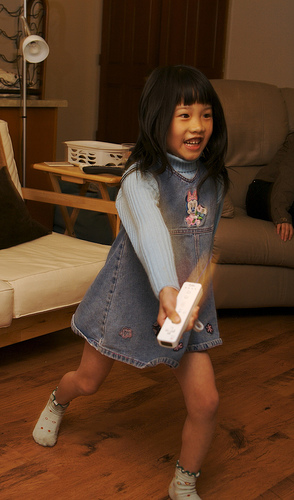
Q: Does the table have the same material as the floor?
A: Yes, both the table and the floor are made of wood.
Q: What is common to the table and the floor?
A: The material, both the table and the floor are wooden.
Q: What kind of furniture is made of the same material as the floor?
A: The table is made of the same material as the floor.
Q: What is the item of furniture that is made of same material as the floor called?
A: The piece of furniture is a table.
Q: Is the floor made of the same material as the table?
A: Yes, both the floor and the table are made of wood.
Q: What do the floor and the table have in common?
A: The material, both the floor and the table are wooden.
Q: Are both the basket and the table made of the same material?
A: No, the basket is made of plastic and the table is made of wood.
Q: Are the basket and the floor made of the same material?
A: No, the basket is made of plastic and the floor is made of wood.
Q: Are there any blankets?
A: Yes, there is a blanket.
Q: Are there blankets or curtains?
A: Yes, there is a blanket.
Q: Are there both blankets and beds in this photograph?
A: No, there is a blanket but no beds.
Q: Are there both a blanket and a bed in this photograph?
A: No, there is a blanket but no beds.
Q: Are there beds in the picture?
A: No, there are no beds.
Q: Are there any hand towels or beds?
A: No, there are no beds or hand towels.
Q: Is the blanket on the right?
A: Yes, the blanket is on the right of the image.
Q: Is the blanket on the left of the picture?
A: No, the blanket is on the right of the image.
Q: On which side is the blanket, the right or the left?
A: The blanket is on the right of the image.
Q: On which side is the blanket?
A: The blanket is on the right of the image.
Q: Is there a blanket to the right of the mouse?
A: Yes, there is a blanket to the right of the mouse.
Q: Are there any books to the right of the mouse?
A: No, there is a blanket to the right of the mouse.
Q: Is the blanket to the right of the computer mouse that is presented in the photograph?
A: Yes, the blanket is to the right of the computer mouse.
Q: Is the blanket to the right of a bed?
A: No, the blanket is to the right of the computer mouse.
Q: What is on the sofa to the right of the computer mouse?
A: The blanket is on the sofa.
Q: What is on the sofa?
A: The blanket is on the sofa.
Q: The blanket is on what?
A: The blanket is on the sofa.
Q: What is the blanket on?
A: The blanket is on the sofa.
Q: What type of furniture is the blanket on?
A: The blanket is on the sofa.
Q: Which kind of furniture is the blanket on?
A: The blanket is on the sofa.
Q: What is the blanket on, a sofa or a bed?
A: The blanket is on a sofa.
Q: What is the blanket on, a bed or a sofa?
A: The blanket is on a sofa.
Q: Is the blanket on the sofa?
A: Yes, the blanket is on the sofa.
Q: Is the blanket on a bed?
A: No, the blanket is on the sofa.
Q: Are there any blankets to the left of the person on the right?
A: Yes, there is a blanket to the left of the person.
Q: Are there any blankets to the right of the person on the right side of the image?
A: No, the blanket is to the left of the person.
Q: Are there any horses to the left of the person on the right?
A: No, there is a blanket to the left of the person.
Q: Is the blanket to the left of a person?
A: Yes, the blanket is to the left of a person.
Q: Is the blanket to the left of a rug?
A: No, the blanket is to the left of a person.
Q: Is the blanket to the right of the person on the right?
A: No, the blanket is to the left of the person.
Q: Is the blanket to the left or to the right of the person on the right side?
A: The blanket is to the left of the person.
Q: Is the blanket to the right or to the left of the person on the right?
A: The blanket is to the left of the person.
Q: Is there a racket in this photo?
A: No, there are no rackets.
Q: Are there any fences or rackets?
A: No, there are no rackets or fences.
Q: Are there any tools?
A: No, there are no tools.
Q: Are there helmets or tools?
A: No, there are no tools or helmets.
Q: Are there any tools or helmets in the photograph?
A: No, there are no tools or helmets.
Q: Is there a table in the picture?
A: Yes, there is a table.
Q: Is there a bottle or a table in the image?
A: Yes, there is a table.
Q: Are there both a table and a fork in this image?
A: No, there is a table but no forks.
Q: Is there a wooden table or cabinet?
A: Yes, there is a wood table.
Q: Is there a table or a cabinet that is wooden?
A: Yes, the table is wooden.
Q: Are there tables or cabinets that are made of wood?
A: Yes, the table is made of wood.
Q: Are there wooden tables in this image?
A: Yes, there is a wood table.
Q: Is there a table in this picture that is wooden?
A: Yes, there is a table that is wooden.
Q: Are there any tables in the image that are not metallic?
A: Yes, there is a wooden table.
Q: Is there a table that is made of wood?
A: Yes, there is a table that is made of wood.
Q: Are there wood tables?
A: Yes, there is a table that is made of wood.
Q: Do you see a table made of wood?
A: Yes, there is a table that is made of wood.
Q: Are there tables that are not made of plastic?
A: Yes, there is a table that is made of wood.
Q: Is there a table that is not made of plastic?
A: Yes, there is a table that is made of wood.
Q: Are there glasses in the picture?
A: No, there are no glasses.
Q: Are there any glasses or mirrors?
A: No, there are no glasses or mirrors.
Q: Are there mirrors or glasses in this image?
A: No, there are no glasses or mirrors.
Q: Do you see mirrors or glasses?
A: No, there are no glasses or mirrors.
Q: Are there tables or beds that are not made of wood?
A: No, there is a table but it is made of wood.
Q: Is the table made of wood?
A: Yes, the table is made of wood.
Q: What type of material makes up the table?
A: The table is made of wood.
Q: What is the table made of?
A: The table is made of wood.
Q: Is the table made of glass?
A: No, the table is made of wood.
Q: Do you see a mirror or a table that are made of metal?
A: No, there is a table but it is made of wood.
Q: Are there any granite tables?
A: No, there is a table but it is made of wood.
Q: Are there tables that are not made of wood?
A: No, there is a table but it is made of wood.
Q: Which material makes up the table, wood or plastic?
A: The table is made of wood.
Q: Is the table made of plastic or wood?
A: The table is made of wood.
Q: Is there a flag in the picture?
A: No, there are no flags.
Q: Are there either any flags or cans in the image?
A: No, there are no flags or cans.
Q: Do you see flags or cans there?
A: No, there are no flags or cans.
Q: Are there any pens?
A: No, there are no pens.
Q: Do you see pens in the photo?
A: No, there are no pens.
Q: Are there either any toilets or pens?
A: No, there are no pens or toilets.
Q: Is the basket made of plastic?
A: Yes, the basket is made of plastic.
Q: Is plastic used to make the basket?
A: Yes, the basket is made of plastic.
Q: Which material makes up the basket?
A: The basket is made of plastic.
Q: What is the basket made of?
A: The basket is made of plastic.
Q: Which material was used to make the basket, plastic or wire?
A: The basket is made of plastic.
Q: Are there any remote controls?
A: Yes, there is a remote control.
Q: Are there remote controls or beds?
A: Yes, there is a remote control.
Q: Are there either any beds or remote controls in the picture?
A: Yes, there is a remote control.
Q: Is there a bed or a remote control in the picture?
A: Yes, there is a remote control.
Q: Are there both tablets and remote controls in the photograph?
A: No, there is a remote control but no tablets.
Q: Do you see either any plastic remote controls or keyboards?
A: Yes, there is a plastic remote control.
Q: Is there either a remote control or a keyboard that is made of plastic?
A: Yes, the remote control is made of plastic.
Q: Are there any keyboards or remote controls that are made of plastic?
A: Yes, the remote control is made of plastic.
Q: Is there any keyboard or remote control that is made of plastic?
A: Yes, the remote control is made of plastic.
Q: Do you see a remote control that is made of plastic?
A: Yes, there is a remote control that is made of plastic.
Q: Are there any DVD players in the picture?
A: No, there are no DVD players.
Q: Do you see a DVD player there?
A: No, there are no DVD players.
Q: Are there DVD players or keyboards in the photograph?
A: No, there are no DVD players or keyboards.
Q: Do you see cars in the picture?
A: No, there are no cars.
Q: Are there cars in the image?
A: No, there are no cars.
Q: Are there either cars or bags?
A: No, there are no cars or bags.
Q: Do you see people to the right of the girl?
A: Yes, there is a person to the right of the girl.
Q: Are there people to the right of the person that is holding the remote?
A: Yes, there is a person to the right of the girl.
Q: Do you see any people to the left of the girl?
A: No, the person is to the right of the girl.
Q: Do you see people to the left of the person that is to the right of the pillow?
A: No, the person is to the right of the girl.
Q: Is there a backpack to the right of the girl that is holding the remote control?
A: No, there is a person to the right of the girl.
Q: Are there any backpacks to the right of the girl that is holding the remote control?
A: No, there is a person to the right of the girl.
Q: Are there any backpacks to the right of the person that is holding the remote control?
A: No, there is a person to the right of the girl.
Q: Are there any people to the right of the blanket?
A: Yes, there is a person to the right of the blanket.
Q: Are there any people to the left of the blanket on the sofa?
A: No, the person is to the right of the blanket.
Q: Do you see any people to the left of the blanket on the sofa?
A: No, the person is to the right of the blanket.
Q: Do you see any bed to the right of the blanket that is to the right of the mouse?
A: No, there is a person to the right of the blanket.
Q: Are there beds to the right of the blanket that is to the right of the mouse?
A: No, there is a person to the right of the blanket.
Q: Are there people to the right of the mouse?
A: Yes, there is a person to the right of the mouse.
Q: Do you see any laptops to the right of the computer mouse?
A: No, there is a person to the right of the computer mouse.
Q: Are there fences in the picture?
A: No, there are no fences.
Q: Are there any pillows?
A: Yes, there is a pillow.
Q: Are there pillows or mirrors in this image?
A: Yes, there is a pillow.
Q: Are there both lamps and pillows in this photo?
A: Yes, there are both a pillow and a lamp.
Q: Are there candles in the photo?
A: No, there are no candles.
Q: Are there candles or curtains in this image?
A: No, there are no candles or curtains.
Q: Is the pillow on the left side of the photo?
A: Yes, the pillow is on the left of the image.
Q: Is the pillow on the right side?
A: No, the pillow is on the left of the image.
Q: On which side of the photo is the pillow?
A: The pillow is on the left of the image.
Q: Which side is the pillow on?
A: The pillow is on the left of the image.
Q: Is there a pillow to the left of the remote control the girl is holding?
A: Yes, there is a pillow to the left of the remote control.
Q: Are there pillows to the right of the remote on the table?
A: No, the pillow is to the left of the remote control.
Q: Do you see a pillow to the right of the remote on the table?
A: No, the pillow is to the left of the remote control.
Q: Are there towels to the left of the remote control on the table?
A: No, there is a pillow to the left of the remote.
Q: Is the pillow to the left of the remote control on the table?
A: Yes, the pillow is to the left of the remote.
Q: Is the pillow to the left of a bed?
A: No, the pillow is to the left of the remote.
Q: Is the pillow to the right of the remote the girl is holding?
A: No, the pillow is to the left of the remote control.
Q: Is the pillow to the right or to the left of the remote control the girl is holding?
A: The pillow is to the left of the remote.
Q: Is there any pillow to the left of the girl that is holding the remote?
A: Yes, there is a pillow to the left of the girl.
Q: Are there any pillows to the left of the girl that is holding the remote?
A: Yes, there is a pillow to the left of the girl.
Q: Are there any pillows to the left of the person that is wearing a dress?
A: Yes, there is a pillow to the left of the girl.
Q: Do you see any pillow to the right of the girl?
A: No, the pillow is to the left of the girl.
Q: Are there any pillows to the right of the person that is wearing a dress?
A: No, the pillow is to the left of the girl.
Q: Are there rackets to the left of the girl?
A: No, there is a pillow to the left of the girl.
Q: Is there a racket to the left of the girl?
A: No, there is a pillow to the left of the girl.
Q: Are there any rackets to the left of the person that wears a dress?
A: No, there is a pillow to the left of the girl.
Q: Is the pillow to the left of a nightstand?
A: No, the pillow is to the left of the girl.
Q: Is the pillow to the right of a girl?
A: No, the pillow is to the left of a girl.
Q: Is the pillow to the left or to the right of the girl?
A: The pillow is to the left of the girl.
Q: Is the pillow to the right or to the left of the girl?
A: The pillow is to the left of the girl.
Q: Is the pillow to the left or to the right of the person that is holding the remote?
A: The pillow is to the left of the girl.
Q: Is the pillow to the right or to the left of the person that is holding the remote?
A: The pillow is to the left of the girl.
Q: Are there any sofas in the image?
A: Yes, there is a sofa.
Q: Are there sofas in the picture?
A: Yes, there is a sofa.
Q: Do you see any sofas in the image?
A: Yes, there is a sofa.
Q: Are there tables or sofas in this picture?
A: Yes, there is a sofa.